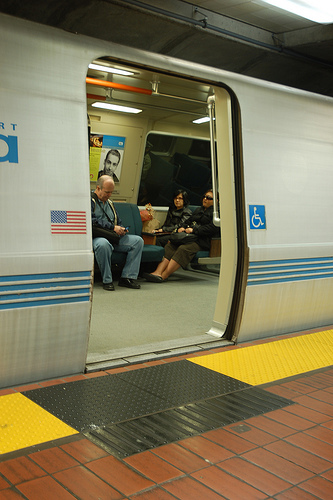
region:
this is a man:
[99, 171, 138, 280]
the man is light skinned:
[103, 181, 116, 190]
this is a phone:
[125, 225, 131, 230]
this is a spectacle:
[204, 194, 213, 198]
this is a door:
[100, 57, 228, 303]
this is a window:
[149, 134, 196, 174]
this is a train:
[267, 106, 329, 257]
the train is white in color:
[288, 131, 304, 194]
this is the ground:
[237, 420, 327, 488]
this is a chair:
[146, 236, 166, 260]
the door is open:
[94, 109, 227, 350]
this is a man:
[93, 170, 127, 282]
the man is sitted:
[93, 176, 132, 283]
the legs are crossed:
[147, 258, 179, 281]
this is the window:
[158, 141, 203, 180]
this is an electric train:
[292, 191, 320, 238]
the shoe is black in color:
[117, 279, 137, 288]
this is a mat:
[113, 374, 201, 437]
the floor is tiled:
[236, 444, 313, 494]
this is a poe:
[122, 81, 150, 97]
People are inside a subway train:
[85, 70, 230, 338]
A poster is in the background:
[88, 130, 123, 184]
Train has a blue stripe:
[0, 252, 332, 310]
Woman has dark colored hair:
[163, 187, 191, 214]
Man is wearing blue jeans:
[93, 231, 146, 284]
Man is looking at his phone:
[93, 174, 133, 239]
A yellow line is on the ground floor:
[3, 319, 332, 464]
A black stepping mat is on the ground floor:
[28, 345, 269, 468]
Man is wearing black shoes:
[100, 269, 148, 300]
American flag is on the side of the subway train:
[44, 207, 89, 237]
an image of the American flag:
[49, 208, 87, 235]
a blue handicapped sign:
[248, 203, 267, 229]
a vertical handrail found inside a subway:
[205, 91, 222, 227]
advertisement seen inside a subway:
[91, 131, 127, 185]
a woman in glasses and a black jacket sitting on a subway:
[152, 187, 192, 236]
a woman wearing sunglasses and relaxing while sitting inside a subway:
[144, 189, 218, 281]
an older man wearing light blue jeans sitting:
[91, 174, 143, 291]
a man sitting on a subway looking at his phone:
[90, 174, 144, 291]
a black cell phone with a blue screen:
[123, 224, 129, 234]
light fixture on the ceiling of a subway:
[88, 99, 143, 114]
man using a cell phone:
[91, 171, 142, 291]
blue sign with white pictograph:
[246, 197, 269, 234]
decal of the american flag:
[48, 208, 89, 236]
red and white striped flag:
[47, 207, 88, 235]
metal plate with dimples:
[21, 358, 251, 431]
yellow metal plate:
[186, 327, 331, 386]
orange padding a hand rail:
[85, 75, 155, 98]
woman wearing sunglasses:
[201, 188, 217, 208]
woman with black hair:
[168, 186, 191, 230]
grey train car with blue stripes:
[1, 12, 328, 382]